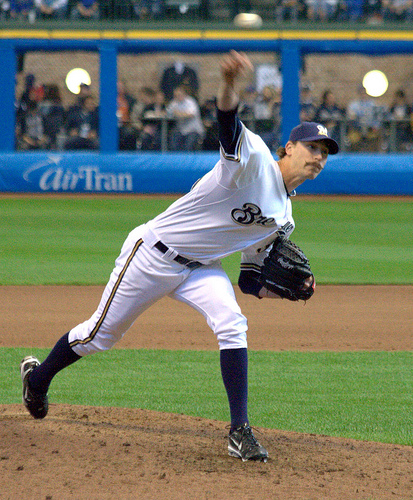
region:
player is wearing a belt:
[122, 219, 252, 306]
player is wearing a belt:
[149, 235, 206, 286]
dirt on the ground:
[83, 425, 163, 471]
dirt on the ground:
[108, 402, 248, 498]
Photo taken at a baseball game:
[0, 23, 404, 490]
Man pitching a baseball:
[63, 103, 326, 471]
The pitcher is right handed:
[49, 109, 342, 468]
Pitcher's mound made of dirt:
[0, 400, 410, 494]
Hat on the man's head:
[269, 109, 353, 156]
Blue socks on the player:
[23, 331, 264, 440]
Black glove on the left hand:
[247, 238, 329, 304]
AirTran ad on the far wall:
[17, 154, 159, 193]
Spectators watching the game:
[17, 70, 407, 150]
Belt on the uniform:
[135, 232, 209, 276]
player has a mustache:
[278, 116, 343, 200]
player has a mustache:
[291, 132, 360, 215]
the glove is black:
[244, 221, 328, 315]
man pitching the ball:
[4, 36, 348, 472]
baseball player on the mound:
[15, 42, 356, 470]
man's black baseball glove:
[257, 226, 316, 312]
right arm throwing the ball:
[210, 43, 253, 188]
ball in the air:
[232, 9, 270, 33]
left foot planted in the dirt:
[220, 414, 279, 470]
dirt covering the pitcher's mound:
[0, 394, 411, 497]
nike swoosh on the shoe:
[229, 434, 244, 452]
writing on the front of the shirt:
[227, 191, 276, 232]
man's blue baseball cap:
[285, 117, 343, 149]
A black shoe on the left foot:
[227, 429, 266, 460]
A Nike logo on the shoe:
[226, 435, 243, 449]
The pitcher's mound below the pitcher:
[1, 403, 412, 496]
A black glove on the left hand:
[264, 237, 313, 297]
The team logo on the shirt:
[230, 198, 273, 231]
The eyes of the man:
[307, 143, 328, 153]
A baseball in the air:
[238, 11, 258, 29]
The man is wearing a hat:
[294, 123, 338, 146]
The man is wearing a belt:
[144, 229, 204, 268]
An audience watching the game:
[14, 70, 411, 152]